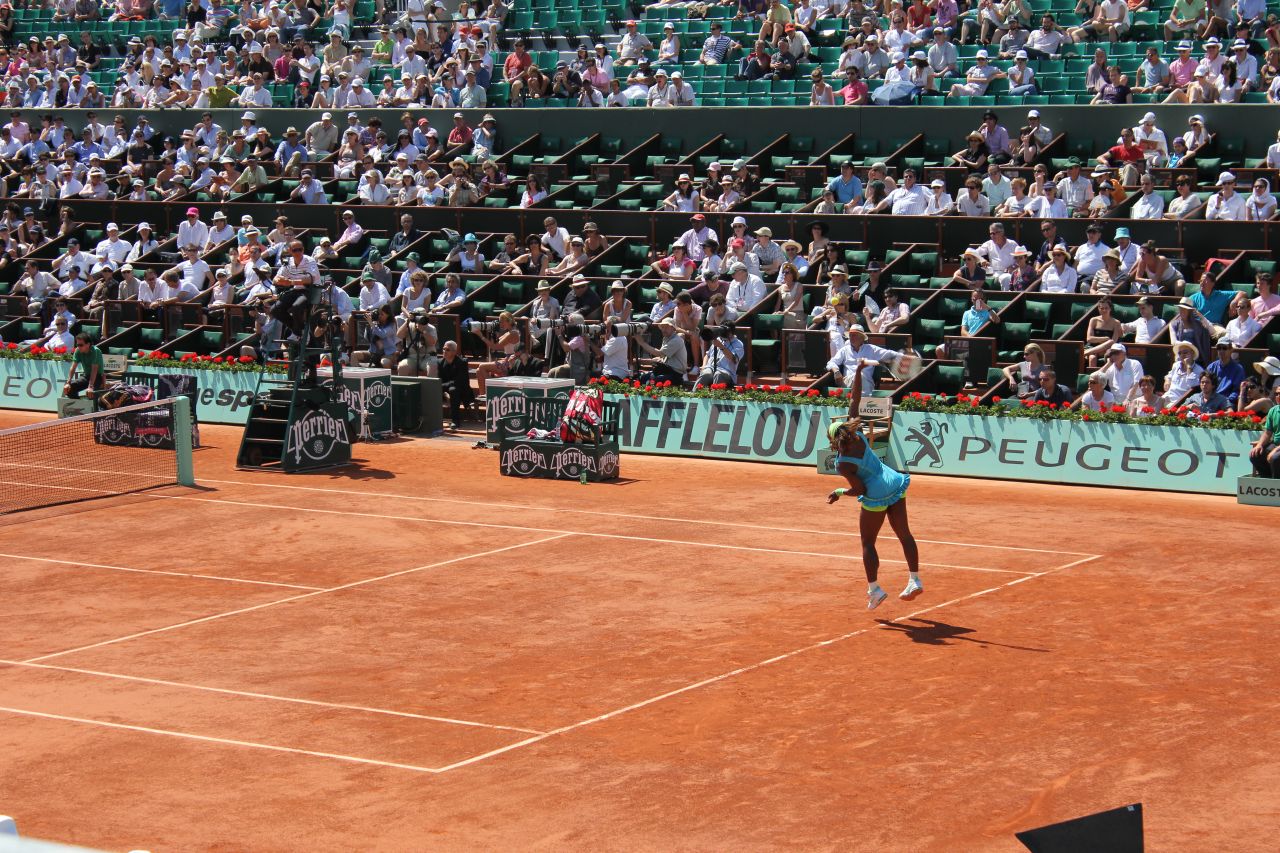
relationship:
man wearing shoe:
[826, 359, 924, 612] [861, 569, 899, 620]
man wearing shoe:
[826, 359, 924, 612] [899, 565, 933, 619]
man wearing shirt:
[723, 256, 761, 320] [727, 282, 761, 320]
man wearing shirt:
[826, 359, 924, 612] [1098, 366, 1145, 404]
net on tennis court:
[7, 390, 199, 516] [5, 384, 1279, 848]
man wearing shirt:
[349, 158, 396, 209] [338, 183, 396, 208]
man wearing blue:
[826, 359, 924, 612] [824, 426, 915, 526]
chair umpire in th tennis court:
[252, 236, 326, 320] [5, 384, 1279, 848]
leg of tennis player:
[851, 505, 889, 611] [813, 359, 922, 607]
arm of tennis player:
[828, 461, 864, 499] [828, 355, 924, 603]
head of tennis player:
[818, 408, 867, 455] [813, 359, 922, 607]